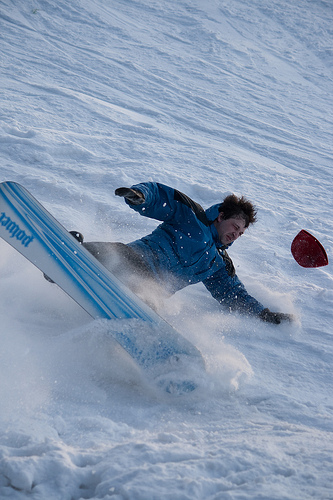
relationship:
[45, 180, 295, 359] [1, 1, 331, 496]
man falling in snow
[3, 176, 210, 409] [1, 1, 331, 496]
snowboard kicked up snow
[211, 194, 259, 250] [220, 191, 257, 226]
head has hair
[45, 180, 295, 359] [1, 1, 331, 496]
man about to eat snow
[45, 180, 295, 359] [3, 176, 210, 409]
man riding snowboard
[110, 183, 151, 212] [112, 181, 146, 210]
hand inside glove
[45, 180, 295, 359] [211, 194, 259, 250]
man has head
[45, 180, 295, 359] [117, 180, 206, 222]
man has arm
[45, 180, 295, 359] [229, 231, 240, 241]
man has nose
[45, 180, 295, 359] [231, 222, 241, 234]
man has eye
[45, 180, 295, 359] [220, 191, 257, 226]
man has hair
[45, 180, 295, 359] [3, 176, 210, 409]
man falling off of snowboard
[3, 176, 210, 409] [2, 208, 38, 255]
snowboard has logo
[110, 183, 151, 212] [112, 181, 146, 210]
hand has glove